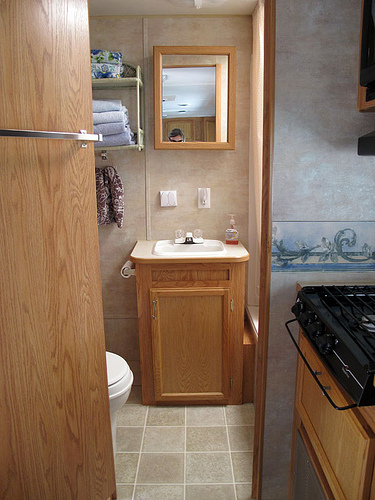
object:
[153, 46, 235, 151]
mirror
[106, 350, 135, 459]
toilet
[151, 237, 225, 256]
sink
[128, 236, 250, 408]
cabinet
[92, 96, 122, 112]
towel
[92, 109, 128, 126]
towel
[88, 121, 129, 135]
towel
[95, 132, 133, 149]
towel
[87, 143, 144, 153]
shelf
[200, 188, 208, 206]
nightlight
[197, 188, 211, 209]
outlet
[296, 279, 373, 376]
stove top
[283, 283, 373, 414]
stove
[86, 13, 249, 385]
wall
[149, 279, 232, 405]
cupboard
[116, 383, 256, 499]
floor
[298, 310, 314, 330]
knobs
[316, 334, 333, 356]
knob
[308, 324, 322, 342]
knob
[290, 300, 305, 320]
knob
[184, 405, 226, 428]
tile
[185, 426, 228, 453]
tile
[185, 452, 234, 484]
tile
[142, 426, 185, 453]
tile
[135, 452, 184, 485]
tile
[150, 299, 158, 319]
handle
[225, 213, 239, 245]
soap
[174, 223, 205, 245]
faucet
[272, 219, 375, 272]
design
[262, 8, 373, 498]
wall